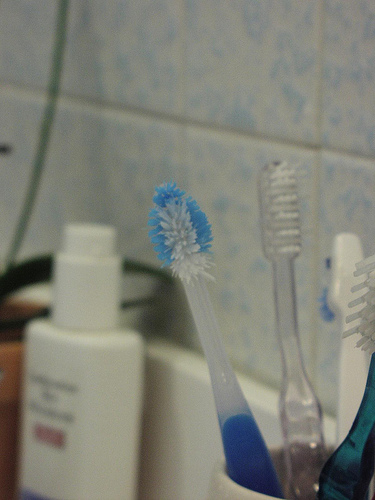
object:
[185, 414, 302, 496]
brush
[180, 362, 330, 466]
brush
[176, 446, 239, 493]
cup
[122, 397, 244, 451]
board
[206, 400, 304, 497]
brush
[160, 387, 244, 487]
wall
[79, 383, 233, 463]
board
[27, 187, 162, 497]
bottle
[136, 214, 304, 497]
brush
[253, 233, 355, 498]
brush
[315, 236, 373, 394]
brush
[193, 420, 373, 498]
cup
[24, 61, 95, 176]
plant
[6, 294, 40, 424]
pot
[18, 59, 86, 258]
plant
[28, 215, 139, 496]
lotion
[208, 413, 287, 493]
handle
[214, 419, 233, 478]
edge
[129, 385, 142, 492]
edge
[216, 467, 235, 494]
edge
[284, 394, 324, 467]
handle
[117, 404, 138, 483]
bottle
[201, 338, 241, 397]
handle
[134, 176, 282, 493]
toothbrush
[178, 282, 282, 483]
handle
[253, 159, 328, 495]
toothbrush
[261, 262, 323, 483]
handle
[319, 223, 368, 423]
toothbrush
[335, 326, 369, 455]
handle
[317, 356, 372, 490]
toothbrush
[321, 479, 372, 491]
handle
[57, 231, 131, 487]
bottle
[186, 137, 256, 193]
tile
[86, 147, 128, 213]
tile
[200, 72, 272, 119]
tile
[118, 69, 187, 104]
tile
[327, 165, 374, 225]
tile